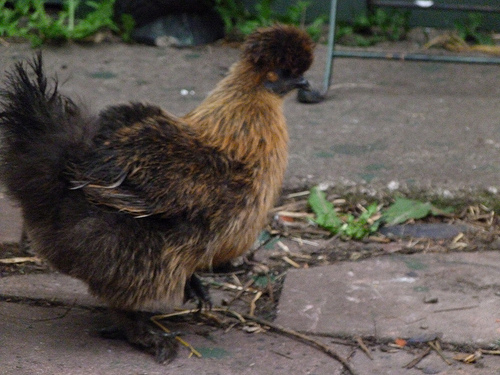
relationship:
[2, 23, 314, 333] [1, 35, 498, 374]
chicken standing on ground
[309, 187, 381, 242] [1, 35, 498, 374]
leaf growing out ground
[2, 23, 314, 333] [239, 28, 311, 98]
chicken has head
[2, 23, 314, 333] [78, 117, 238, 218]
chicken has wing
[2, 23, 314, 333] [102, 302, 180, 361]
chicken has foot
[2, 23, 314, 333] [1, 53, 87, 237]
chicken has tail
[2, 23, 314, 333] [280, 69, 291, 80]
chicken has eye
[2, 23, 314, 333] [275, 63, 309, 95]
chicken has face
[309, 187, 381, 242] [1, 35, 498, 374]
leaf laying on ground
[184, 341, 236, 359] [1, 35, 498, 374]
paint spot painted on ground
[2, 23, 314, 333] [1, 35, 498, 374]
chicken walking on ground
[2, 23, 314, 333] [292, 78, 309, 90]
chicken has bill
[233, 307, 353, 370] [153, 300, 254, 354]
branch next to straw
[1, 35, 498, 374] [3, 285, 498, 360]
ground has crack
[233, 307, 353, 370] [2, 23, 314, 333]
branch under chicken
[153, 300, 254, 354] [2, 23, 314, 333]
straw under chicken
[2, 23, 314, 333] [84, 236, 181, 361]
chicken has leg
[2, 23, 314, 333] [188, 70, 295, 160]
chicken has neck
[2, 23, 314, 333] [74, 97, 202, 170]
chicken has back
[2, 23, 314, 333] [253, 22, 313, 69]
chicken has top knot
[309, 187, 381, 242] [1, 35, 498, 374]
leaf coming from ground